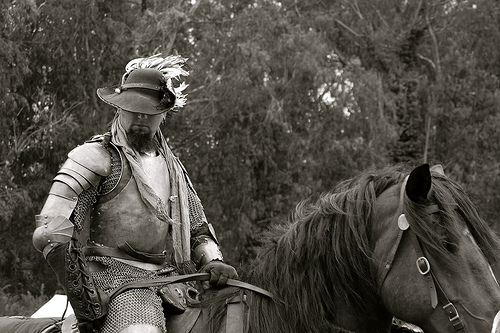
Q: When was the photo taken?
A: Duringthe daytime.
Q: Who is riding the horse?
A: A man.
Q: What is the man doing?
A: Riding.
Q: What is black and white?
A: The whole photo.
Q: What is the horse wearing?
A: Saddle.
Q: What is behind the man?
A: Trees.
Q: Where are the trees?
A: Behind the man.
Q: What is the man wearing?
A: Hat.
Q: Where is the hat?
A: On the man.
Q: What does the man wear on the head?
A: A hat.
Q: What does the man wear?
A: Chain maille.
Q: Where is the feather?
A: In the hat.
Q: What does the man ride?
A: The horse.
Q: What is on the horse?
A: The bridal.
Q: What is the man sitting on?
A: The saddle.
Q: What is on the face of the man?
A: Beard.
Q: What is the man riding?
A: A horse.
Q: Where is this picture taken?
A: A forest.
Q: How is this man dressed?
A: Like a knight.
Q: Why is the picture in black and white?
A: For a vintage look.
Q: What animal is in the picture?
A: Horse.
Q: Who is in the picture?
A: A man dressed as a knight.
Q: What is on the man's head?
A: A hat.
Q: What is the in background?
A: A tree.